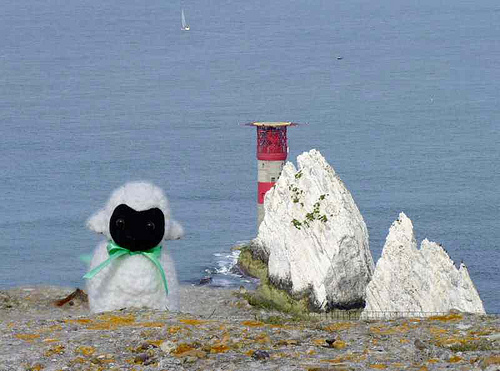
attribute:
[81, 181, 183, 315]
sheep — white, stuffed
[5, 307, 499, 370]
ground — rocky, grey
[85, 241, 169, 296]
ribbon — green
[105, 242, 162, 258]
ribbon — green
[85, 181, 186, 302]
animal — white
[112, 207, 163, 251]
face — black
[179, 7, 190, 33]
boat — white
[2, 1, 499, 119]
water — blue, calm, still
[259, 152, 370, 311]
rock — big, large, white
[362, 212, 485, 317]
rock — gray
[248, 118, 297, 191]
tower — red, white, rusty